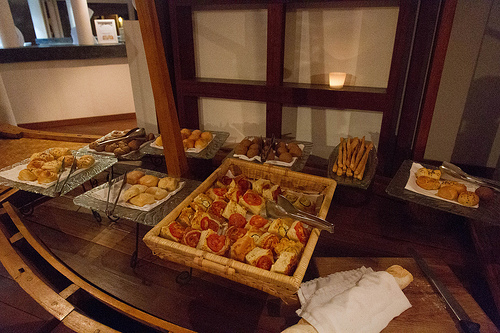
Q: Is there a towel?
A: Yes, there is a towel.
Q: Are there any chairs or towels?
A: Yes, there is a towel.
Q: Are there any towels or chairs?
A: Yes, there is a towel.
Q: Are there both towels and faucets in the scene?
A: No, there is a towel but no faucets.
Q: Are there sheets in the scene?
A: No, there are no sheets.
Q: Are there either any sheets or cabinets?
A: No, there are no sheets or cabinets.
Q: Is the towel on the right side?
A: Yes, the towel is on the right of the image.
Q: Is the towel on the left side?
A: No, the towel is on the right of the image.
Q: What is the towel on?
A: The towel is on the table.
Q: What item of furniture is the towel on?
A: The towel is on the table.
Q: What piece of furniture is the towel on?
A: The towel is on the table.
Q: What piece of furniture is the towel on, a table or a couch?
A: The towel is on a table.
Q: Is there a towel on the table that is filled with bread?
A: Yes, there is a towel on the table.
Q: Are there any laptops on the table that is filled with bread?
A: No, there is a towel on the table.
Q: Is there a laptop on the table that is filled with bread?
A: No, there is a towel on the table.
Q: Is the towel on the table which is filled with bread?
A: Yes, the towel is on the table.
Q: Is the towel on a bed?
A: No, the towel is on the table.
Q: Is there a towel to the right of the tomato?
A: Yes, there is a towel to the right of the tomato.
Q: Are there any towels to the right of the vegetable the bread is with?
A: Yes, there is a towel to the right of the tomato.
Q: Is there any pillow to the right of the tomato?
A: No, there is a towel to the right of the tomato.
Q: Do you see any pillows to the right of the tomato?
A: No, there is a towel to the right of the tomato.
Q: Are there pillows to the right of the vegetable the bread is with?
A: No, there is a towel to the right of the tomato.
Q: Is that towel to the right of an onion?
A: No, the towel is to the right of the tomato.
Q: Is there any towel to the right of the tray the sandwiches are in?
A: Yes, there is a towel to the right of the tray.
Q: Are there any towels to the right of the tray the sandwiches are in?
A: Yes, there is a towel to the right of the tray.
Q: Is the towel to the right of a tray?
A: Yes, the towel is to the right of a tray.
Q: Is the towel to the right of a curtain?
A: No, the towel is to the right of a tray.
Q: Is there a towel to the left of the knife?
A: Yes, there is a towel to the left of the knife.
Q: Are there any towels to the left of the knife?
A: Yes, there is a towel to the left of the knife.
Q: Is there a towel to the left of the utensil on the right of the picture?
A: Yes, there is a towel to the left of the knife.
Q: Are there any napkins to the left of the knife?
A: No, there is a towel to the left of the knife.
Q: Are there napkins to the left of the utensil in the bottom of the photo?
A: No, there is a towel to the left of the knife.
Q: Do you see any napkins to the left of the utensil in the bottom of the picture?
A: No, there is a towel to the left of the knife.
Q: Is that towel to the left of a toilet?
A: No, the towel is to the left of the knife.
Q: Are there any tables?
A: Yes, there is a table.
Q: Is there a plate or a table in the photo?
A: Yes, there is a table.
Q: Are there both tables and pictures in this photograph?
A: No, there is a table but no pictures.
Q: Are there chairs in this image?
A: No, there are no chairs.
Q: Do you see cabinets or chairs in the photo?
A: No, there are no chairs or cabinets.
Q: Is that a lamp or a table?
A: That is a table.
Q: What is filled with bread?
A: The table is filled with bread.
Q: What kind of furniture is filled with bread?
A: The piece of furniture is a table.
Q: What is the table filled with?
A: The table is filled with bread.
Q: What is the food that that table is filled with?
A: The food is a bread.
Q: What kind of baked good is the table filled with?
A: The table is filled with bread.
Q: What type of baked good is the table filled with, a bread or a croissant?
A: The table is filled with a bread.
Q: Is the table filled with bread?
A: Yes, the table is filled with bread.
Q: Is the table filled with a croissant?
A: No, the table is filled with bread.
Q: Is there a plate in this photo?
A: Yes, there is a plate.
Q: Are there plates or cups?
A: Yes, there is a plate.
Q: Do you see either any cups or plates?
A: Yes, there is a plate.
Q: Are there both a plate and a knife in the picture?
A: Yes, there are both a plate and a knife.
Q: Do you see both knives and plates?
A: Yes, there are both a plate and a knife.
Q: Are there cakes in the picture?
A: No, there are no cakes.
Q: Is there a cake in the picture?
A: No, there are no cakes.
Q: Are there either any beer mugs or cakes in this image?
A: No, there are no cakes or beer mugs.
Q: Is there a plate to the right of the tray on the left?
A: Yes, there is a plate to the right of the tray.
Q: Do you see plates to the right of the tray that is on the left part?
A: Yes, there is a plate to the right of the tray.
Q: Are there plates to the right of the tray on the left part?
A: Yes, there is a plate to the right of the tray.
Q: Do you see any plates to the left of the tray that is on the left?
A: No, the plate is to the right of the tray.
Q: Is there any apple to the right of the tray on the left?
A: No, there is a plate to the right of the tray.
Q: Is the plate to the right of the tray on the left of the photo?
A: Yes, the plate is to the right of the tray.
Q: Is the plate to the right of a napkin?
A: No, the plate is to the right of the tray.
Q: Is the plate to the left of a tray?
A: No, the plate is to the right of a tray.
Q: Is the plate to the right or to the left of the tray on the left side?
A: The plate is to the right of the tray.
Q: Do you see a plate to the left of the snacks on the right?
A: Yes, there is a plate to the left of the snacks.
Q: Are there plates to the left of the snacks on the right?
A: Yes, there is a plate to the left of the snacks.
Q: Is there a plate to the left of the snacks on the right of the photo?
A: Yes, there is a plate to the left of the snacks.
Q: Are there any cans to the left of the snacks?
A: No, there is a plate to the left of the snacks.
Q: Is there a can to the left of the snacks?
A: No, there is a plate to the left of the snacks.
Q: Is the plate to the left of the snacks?
A: Yes, the plate is to the left of the snacks.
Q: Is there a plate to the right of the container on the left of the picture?
A: Yes, there is a plate to the right of the container.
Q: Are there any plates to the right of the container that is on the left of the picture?
A: Yes, there is a plate to the right of the container.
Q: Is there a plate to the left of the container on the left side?
A: No, the plate is to the right of the container.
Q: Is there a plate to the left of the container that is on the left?
A: No, the plate is to the right of the container.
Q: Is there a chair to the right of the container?
A: No, there is a plate to the right of the container.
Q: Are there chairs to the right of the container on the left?
A: No, there is a plate to the right of the container.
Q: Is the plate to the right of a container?
A: Yes, the plate is to the right of a container.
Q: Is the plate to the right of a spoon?
A: No, the plate is to the right of a container.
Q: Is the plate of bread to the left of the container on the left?
A: No, the plate is to the right of the container.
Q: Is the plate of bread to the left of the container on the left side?
A: No, the plate is to the right of the container.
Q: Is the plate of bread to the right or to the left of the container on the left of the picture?
A: The plate is to the right of the container.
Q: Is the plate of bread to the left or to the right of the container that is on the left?
A: The plate is to the right of the container.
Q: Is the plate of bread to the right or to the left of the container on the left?
A: The plate is to the right of the container.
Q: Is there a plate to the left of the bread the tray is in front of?
A: Yes, there is a plate to the left of the bread.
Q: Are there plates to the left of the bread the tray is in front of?
A: Yes, there is a plate to the left of the bread.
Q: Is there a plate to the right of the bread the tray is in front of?
A: No, the plate is to the left of the bread.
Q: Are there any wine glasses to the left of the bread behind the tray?
A: No, there is a plate to the left of the bread.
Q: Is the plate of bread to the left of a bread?
A: Yes, the plate is to the left of a bread.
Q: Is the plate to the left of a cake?
A: No, the plate is to the left of a bread.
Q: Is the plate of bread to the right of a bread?
A: No, the plate is to the left of a bread.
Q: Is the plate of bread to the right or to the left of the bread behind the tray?
A: The plate is to the left of the bread.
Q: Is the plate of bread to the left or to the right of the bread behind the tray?
A: The plate is to the left of the bread.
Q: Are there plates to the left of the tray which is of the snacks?
A: Yes, there is a plate to the left of the tray.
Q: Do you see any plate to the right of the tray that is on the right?
A: No, the plate is to the left of the tray.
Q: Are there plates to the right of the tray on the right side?
A: No, the plate is to the left of the tray.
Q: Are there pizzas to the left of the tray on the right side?
A: No, there is a plate to the left of the tray.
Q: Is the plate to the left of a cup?
A: No, the plate is to the left of a tray.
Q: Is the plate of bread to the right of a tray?
A: No, the plate is to the left of a tray.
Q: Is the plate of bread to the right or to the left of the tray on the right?
A: The plate is to the left of the tray.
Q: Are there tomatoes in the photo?
A: Yes, there is a tomato.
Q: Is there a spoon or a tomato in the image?
A: Yes, there is a tomato.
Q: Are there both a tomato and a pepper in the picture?
A: No, there is a tomato but no peppers.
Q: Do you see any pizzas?
A: No, there are no pizzas.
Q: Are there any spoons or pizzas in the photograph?
A: No, there are no pizzas or spoons.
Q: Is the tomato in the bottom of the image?
A: Yes, the tomato is in the bottom of the image.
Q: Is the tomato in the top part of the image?
A: No, the tomato is in the bottom of the image.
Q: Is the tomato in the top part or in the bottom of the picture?
A: The tomato is in the bottom of the image.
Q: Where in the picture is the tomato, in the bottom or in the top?
A: The tomato is in the bottom of the image.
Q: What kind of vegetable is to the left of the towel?
A: The vegetable is a tomato.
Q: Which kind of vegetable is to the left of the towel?
A: The vegetable is a tomato.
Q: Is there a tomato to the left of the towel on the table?
A: Yes, there is a tomato to the left of the towel.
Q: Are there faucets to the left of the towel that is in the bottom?
A: No, there is a tomato to the left of the towel.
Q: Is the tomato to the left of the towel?
A: Yes, the tomato is to the left of the towel.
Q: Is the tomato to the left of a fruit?
A: No, the tomato is to the left of the towel.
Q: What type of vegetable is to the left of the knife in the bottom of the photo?
A: The vegetable is a tomato.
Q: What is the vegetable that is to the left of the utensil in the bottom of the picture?
A: The vegetable is a tomato.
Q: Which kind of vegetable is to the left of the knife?
A: The vegetable is a tomato.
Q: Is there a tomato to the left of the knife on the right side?
A: Yes, there is a tomato to the left of the knife.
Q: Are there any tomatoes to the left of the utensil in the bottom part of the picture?
A: Yes, there is a tomato to the left of the knife.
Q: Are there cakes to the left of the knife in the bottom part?
A: No, there is a tomato to the left of the knife.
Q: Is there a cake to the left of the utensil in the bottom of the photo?
A: No, there is a tomato to the left of the knife.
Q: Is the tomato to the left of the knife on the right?
A: Yes, the tomato is to the left of the knife.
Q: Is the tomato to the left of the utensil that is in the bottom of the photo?
A: Yes, the tomato is to the left of the knife.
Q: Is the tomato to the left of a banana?
A: No, the tomato is to the left of the knife.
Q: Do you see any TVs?
A: No, there are no tvs.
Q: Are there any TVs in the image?
A: No, there are no tvs.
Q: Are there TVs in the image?
A: No, there are no tvs.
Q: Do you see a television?
A: No, there are no televisions.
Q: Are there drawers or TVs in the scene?
A: No, there are no TVs or drawers.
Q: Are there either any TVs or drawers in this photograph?
A: No, there are no TVs or drawers.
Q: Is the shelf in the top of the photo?
A: Yes, the shelf is in the top of the image.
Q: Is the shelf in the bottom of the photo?
A: No, the shelf is in the top of the image.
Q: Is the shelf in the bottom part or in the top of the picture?
A: The shelf is in the top of the image.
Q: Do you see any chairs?
A: No, there are no chairs.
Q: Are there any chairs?
A: No, there are no chairs.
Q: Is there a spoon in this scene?
A: No, there are no spoons.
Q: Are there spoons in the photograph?
A: No, there are no spoons.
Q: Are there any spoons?
A: No, there are no spoons.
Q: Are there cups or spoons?
A: No, there are no spoons or cups.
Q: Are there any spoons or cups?
A: No, there are no spoons or cups.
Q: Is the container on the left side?
A: Yes, the container is on the left of the image.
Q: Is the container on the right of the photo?
A: No, the container is on the left of the image.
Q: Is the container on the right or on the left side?
A: The container is on the left of the image.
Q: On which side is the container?
A: The container is on the left of the image.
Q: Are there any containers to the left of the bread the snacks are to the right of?
A: Yes, there is a container to the left of the bread.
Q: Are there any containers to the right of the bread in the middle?
A: No, the container is to the left of the bread.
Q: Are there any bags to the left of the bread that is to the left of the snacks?
A: No, there is a container to the left of the bread.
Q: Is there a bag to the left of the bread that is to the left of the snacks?
A: No, there is a container to the left of the bread.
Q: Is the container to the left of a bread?
A: Yes, the container is to the left of a bread.